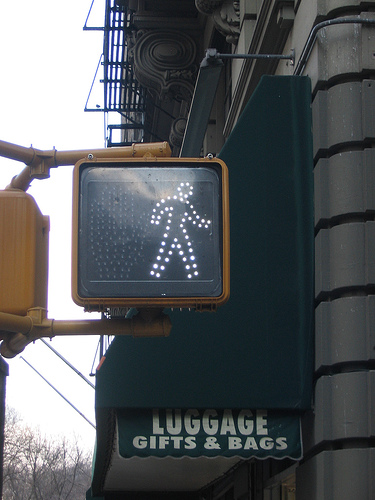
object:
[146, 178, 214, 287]
person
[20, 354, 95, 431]
wires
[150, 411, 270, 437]
writing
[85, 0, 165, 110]
ledge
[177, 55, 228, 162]
light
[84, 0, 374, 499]
building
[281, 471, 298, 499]
window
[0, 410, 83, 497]
trees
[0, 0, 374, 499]
background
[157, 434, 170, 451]
letters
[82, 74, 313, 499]
awning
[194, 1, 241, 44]
work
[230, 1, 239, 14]
leaf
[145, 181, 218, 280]
bulbs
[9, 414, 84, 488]
leaves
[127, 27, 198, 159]
sandstone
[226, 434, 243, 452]
letters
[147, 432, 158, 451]
letters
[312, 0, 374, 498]
wall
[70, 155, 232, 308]
signage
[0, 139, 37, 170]
post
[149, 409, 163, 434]
letter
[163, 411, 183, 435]
letter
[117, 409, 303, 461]
sign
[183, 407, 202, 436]
letter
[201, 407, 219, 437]
letter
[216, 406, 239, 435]
letter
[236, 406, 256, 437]
letter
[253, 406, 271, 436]
letter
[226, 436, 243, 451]
letter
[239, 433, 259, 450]
letter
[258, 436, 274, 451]
letter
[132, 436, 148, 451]
letters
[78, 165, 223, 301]
lights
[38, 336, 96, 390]
power cables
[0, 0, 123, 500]
sky